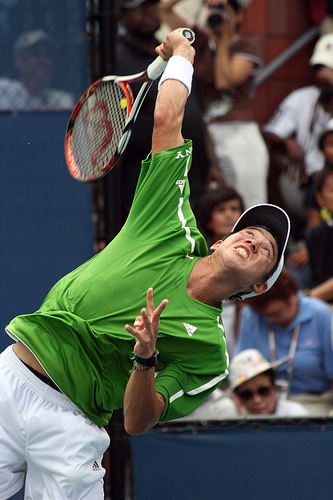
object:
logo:
[181, 320, 197, 337]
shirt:
[4, 139, 230, 430]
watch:
[129, 349, 161, 370]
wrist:
[132, 351, 159, 370]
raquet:
[64, 28, 196, 183]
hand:
[155, 30, 195, 55]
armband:
[157, 54, 195, 98]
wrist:
[171, 44, 196, 62]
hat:
[230, 202, 291, 302]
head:
[210, 222, 285, 294]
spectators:
[0, 0, 333, 419]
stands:
[0, 0, 332, 420]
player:
[0, 26, 290, 499]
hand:
[124, 286, 169, 358]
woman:
[200, 348, 309, 420]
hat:
[213, 347, 292, 404]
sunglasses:
[240, 385, 271, 400]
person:
[232, 272, 333, 417]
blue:
[233, 290, 332, 396]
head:
[249, 265, 300, 327]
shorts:
[0, 341, 111, 499]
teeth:
[235, 245, 249, 259]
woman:
[192, 0, 263, 206]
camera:
[205, 12, 226, 30]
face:
[219, 226, 278, 285]